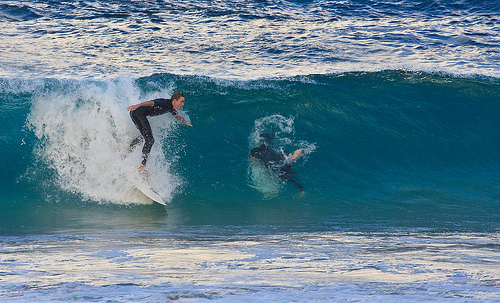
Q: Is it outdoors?
A: Yes, it is outdoors.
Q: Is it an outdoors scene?
A: Yes, it is outdoors.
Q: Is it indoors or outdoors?
A: It is outdoors.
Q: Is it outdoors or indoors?
A: It is outdoors.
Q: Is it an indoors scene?
A: No, it is outdoors.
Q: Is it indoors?
A: No, it is outdoors.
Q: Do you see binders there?
A: No, there are no binders.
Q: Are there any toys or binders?
A: No, there are no binders or toys.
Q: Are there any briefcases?
A: No, there are no briefcases.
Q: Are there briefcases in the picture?
A: No, there are no briefcases.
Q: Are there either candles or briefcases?
A: No, there are no briefcases or candles.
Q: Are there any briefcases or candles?
A: No, there are no briefcases or candles.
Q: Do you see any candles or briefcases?
A: No, there are no briefcases or candles.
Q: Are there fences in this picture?
A: No, there are no fences.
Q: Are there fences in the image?
A: No, there are no fences.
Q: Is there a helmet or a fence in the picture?
A: No, there are no fences or helmets.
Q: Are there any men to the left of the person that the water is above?
A: Yes, there is a man to the left of the person.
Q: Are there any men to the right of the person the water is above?
A: No, the man is to the left of the person.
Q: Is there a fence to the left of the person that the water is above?
A: No, there is a man to the left of the person.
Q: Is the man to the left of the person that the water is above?
A: Yes, the man is to the left of the person.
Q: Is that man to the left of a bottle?
A: No, the man is to the left of the person.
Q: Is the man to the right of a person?
A: No, the man is to the left of a person.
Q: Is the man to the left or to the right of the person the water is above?
A: The man is to the left of the person.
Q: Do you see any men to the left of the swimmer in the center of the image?
A: Yes, there is a man to the left of the swimmer.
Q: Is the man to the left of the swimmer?
A: Yes, the man is to the left of the swimmer.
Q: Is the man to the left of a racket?
A: No, the man is to the left of the swimmer.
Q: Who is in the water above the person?
A: The man is in the water.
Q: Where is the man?
A: The man is in the water.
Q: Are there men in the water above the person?
A: Yes, there is a man in the water.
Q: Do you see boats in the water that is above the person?
A: No, there is a man in the water.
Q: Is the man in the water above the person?
A: Yes, the man is in the water.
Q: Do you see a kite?
A: No, there are no kites.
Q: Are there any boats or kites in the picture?
A: No, there are no kites or boats.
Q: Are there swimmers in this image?
A: Yes, there is a swimmer.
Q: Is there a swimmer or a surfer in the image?
A: Yes, there is a swimmer.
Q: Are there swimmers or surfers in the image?
A: Yes, there is a swimmer.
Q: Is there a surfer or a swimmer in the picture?
A: Yes, there is a swimmer.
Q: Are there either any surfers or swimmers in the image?
A: Yes, there is a swimmer.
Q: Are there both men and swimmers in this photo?
A: Yes, there are both a swimmer and a man.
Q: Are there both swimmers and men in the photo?
A: Yes, there are both a swimmer and a man.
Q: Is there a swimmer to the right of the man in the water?
A: Yes, there is a swimmer to the right of the man.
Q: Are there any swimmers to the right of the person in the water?
A: Yes, there is a swimmer to the right of the man.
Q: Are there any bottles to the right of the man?
A: No, there is a swimmer to the right of the man.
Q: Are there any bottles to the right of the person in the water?
A: No, there is a swimmer to the right of the man.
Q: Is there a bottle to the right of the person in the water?
A: No, there is a swimmer to the right of the man.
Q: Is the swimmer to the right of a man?
A: Yes, the swimmer is to the right of a man.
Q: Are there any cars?
A: No, there are no cars.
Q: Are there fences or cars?
A: No, there are no cars or fences.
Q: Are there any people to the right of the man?
A: Yes, there is a person to the right of the man.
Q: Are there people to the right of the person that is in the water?
A: Yes, there is a person to the right of the man.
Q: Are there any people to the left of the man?
A: No, the person is to the right of the man.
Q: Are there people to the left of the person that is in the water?
A: No, the person is to the right of the man.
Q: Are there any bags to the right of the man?
A: No, there is a person to the right of the man.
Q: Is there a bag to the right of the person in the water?
A: No, there is a person to the right of the man.